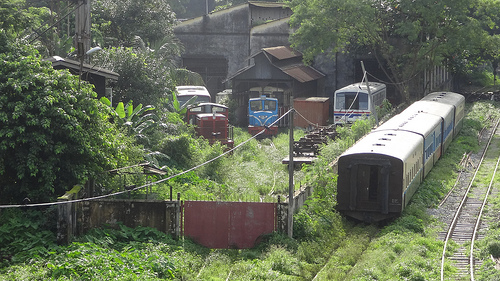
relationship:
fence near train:
[0, 58, 389, 264] [329, 86, 467, 227]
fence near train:
[0, 58, 389, 264] [285, 77, 388, 167]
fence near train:
[0, 58, 389, 264] [245, 82, 285, 138]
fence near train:
[0, 58, 389, 264] [173, 85, 235, 155]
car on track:
[331, 91, 466, 224] [309, 218, 381, 280]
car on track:
[406, 99, 457, 154] [309, 218, 381, 280]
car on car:
[331, 91, 466, 224] [331, 91, 466, 224]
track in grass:
[309, 218, 381, 280] [232, 97, 493, 280]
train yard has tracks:
[0, 0, 499, 280] [431, 108, 498, 279]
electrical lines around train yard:
[0, 72, 425, 209] [39, 44, 499, 276]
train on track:
[310, 46, 499, 243] [299, 84, 494, 276]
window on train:
[335, 93, 371, 111] [323, 61, 389, 128]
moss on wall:
[112, 209, 158, 237] [117, 199, 190, 247]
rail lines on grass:
[297, 207, 379, 279] [3, 209, 199, 276]